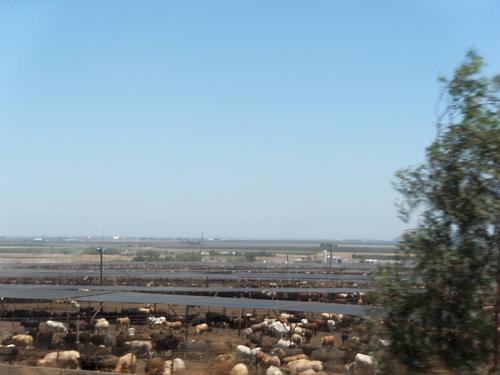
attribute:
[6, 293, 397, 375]
cows — brown, grouped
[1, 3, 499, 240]
sky — blue, clear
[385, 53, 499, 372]
tree — green, leafy, pine, large, tall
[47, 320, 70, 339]
cow — white, grazing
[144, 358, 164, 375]
cow — brown, grazing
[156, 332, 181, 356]
cow — black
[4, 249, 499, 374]
pasture — brown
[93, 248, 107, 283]
pole — wooden, brown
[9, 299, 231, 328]
cows — black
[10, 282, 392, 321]
water — blue